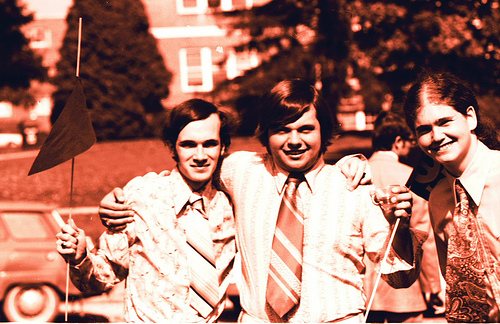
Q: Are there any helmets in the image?
A: No, there are no helmets.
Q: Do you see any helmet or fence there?
A: No, there are no helmets or fences.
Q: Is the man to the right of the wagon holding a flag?
A: Yes, the man is holding a flag.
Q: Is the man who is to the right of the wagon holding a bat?
A: No, the man is holding a flag.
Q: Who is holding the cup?
A: The man is holding the cup.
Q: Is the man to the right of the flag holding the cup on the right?
A: Yes, the man is holding the cup.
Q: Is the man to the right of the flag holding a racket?
A: No, the man is holding the cup.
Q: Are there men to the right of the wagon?
A: Yes, there is a man to the right of the wagon.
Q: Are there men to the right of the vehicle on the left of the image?
A: Yes, there is a man to the right of the wagon.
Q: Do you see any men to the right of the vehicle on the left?
A: Yes, there is a man to the right of the wagon.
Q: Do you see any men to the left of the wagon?
A: No, the man is to the right of the wagon.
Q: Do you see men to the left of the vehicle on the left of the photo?
A: No, the man is to the right of the wagon.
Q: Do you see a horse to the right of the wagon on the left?
A: No, there is a man to the right of the wagon.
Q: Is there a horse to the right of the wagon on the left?
A: No, there is a man to the right of the wagon.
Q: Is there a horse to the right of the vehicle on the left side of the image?
A: No, there is a man to the right of the wagon.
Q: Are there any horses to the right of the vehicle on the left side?
A: No, there is a man to the right of the wagon.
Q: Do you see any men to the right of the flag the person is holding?
A: Yes, there is a man to the right of the flag.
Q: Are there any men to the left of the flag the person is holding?
A: No, the man is to the right of the flag.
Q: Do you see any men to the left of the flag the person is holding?
A: No, the man is to the right of the flag.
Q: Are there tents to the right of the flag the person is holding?
A: No, there is a man to the right of the flag.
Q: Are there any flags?
A: Yes, there is a flag.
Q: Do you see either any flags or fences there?
A: Yes, there is a flag.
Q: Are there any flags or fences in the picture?
A: Yes, there is a flag.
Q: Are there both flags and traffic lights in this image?
A: No, there is a flag but no traffic lights.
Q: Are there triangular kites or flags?
A: Yes, there is a triangular flag.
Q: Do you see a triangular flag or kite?
A: Yes, there is a triangular flag.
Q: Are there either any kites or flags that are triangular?
A: Yes, the flag is triangular.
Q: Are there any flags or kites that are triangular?
A: Yes, the flag is triangular.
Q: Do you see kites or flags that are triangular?
A: Yes, the flag is triangular.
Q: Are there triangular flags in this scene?
A: Yes, there is a triangular flag.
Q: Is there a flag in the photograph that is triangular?
A: Yes, there is a flag that is triangular.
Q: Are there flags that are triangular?
A: Yes, there is a flag that is triangular.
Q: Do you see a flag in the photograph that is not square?
A: Yes, there is a triangular flag.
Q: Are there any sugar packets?
A: No, there are no sugar packets.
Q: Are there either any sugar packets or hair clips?
A: No, there are no sugar packets or hair clips.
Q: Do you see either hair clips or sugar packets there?
A: No, there are no sugar packets or hair clips.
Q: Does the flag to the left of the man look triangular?
A: Yes, the flag is triangular.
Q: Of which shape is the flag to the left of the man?
A: The flag is triangular.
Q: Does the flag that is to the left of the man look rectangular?
A: No, the flag is triangular.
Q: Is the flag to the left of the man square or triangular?
A: The flag is triangular.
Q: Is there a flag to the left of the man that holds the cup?
A: Yes, there is a flag to the left of the man.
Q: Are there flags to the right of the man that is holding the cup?
A: No, the flag is to the left of the man.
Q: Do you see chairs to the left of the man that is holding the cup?
A: No, there is a flag to the left of the man.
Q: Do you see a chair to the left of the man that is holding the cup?
A: No, there is a flag to the left of the man.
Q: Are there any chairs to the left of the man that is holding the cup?
A: No, there is a flag to the left of the man.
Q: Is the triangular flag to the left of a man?
A: Yes, the flag is to the left of a man.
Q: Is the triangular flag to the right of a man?
A: No, the flag is to the left of a man.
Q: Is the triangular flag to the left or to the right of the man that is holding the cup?
A: The flag is to the left of the man.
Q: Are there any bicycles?
A: No, there are no bicycles.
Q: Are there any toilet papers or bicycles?
A: No, there are no bicycles or toilet papers.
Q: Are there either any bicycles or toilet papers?
A: No, there are no bicycles or toilet papers.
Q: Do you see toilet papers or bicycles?
A: No, there are no bicycles or toilet papers.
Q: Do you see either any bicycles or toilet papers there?
A: No, there are no bicycles or toilet papers.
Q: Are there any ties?
A: Yes, there is a tie.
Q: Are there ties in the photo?
A: Yes, there is a tie.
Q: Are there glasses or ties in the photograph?
A: Yes, there is a tie.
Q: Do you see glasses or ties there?
A: Yes, there is a tie.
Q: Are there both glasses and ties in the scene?
A: Yes, there are both a tie and glasses.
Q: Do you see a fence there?
A: No, there are no fences.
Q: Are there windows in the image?
A: Yes, there is a window.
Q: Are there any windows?
A: Yes, there is a window.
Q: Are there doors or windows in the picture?
A: Yes, there is a window.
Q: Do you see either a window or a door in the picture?
A: Yes, there is a window.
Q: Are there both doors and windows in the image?
A: No, there is a window but no doors.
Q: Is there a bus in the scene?
A: No, there are no buses.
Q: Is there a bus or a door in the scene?
A: No, there are no buses or doors.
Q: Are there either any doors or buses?
A: No, there are no buses or doors.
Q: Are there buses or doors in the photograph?
A: No, there are no buses or doors.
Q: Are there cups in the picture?
A: Yes, there is a cup.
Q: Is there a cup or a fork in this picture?
A: Yes, there is a cup.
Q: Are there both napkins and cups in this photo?
A: No, there is a cup but no napkins.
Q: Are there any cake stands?
A: No, there are no cake stands.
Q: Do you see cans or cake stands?
A: No, there are no cake stands or cans.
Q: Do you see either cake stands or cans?
A: No, there are no cake stands or cans.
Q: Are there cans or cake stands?
A: No, there are no cake stands or cans.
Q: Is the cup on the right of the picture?
A: Yes, the cup is on the right of the image.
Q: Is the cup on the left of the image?
A: No, the cup is on the right of the image.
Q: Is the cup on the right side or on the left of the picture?
A: The cup is on the right of the image.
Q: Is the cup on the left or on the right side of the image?
A: The cup is on the right of the image.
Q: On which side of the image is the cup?
A: The cup is on the right of the image.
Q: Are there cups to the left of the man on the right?
A: Yes, there is a cup to the left of the man.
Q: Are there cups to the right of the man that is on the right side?
A: No, the cup is to the left of the man.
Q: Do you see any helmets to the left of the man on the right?
A: No, there is a cup to the left of the man.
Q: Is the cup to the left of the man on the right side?
A: Yes, the cup is to the left of the man.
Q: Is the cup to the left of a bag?
A: No, the cup is to the left of the man.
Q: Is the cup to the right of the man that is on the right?
A: No, the cup is to the left of the man.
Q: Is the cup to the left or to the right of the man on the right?
A: The cup is to the left of the man.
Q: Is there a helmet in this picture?
A: No, there are no helmets.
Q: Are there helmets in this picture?
A: No, there are no helmets.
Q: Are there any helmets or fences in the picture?
A: No, there are no helmets or fences.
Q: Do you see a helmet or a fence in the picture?
A: No, there are no helmets or fences.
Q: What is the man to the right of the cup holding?
A: The man is holding the flag.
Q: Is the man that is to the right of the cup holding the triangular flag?
A: Yes, the man is holding the flag.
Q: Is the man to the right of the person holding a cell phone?
A: No, the man is holding the flag.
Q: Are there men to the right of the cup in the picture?
A: Yes, there is a man to the right of the cup.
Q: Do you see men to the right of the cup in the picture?
A: Yes, there is a man to the right of the cup.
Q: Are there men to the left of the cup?
A: No, the man is to the right of the cup.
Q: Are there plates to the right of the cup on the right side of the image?
A: No, there is a man to the right of the cup.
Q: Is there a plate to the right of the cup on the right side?
A: No, there is a man to the right of the cup.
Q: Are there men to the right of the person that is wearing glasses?
A: Yes, there is a man to the right of the person.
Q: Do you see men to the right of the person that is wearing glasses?
A: Yes, there is a man to the right of the person.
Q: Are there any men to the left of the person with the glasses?
A: No, the man is to the right of the person.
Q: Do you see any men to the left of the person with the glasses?
A: No, the man is to the right of the person.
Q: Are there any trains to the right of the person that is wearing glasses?
A: No, there is a man to the right of the person.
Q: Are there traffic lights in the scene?
A: No, there are no traffic lights.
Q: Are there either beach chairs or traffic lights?
A: No, there are no traffic lights or beach chairs.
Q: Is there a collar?
A: Yes, there is a collar.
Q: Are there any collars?
A: Yes, there is a collar.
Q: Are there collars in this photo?
A: Yes, there is a collar.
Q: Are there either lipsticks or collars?
A: Yes, there is a collar.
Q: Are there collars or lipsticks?
A: Yes, there is a collar.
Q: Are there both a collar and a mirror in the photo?
A: No, there is a collar but no mirrors.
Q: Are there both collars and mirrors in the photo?
A: No, there is a collar but no mirrors.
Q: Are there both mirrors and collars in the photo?
A: No, there is a collar but no mirrors.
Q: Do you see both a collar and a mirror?
A: No, there is a collar but no mirrors.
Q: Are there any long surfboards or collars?
A: Yes, there is a long collar.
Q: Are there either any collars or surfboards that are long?
A: Yes, the collar is long.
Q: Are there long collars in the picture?
A: Yes, there is a long collar.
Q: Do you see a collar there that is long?
A: Yes, there is a collar that is long.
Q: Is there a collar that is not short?
A: Yes, there is a long collar.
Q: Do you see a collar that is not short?
A: Yes, there is a long collar.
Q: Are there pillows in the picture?
A: No, there are no pillows.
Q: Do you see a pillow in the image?
A: No, there are no pillows.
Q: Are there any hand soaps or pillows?
A: No, there are no pillows or hand soaps.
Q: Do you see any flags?
A: Yes, there is a flag.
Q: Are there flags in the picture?
A: Yes, there is a flag.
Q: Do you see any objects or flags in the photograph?
A: Yes, there is a flag.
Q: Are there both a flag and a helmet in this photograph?
A: No, there is a flag but no helmets.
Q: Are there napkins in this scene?
A: No, there are no napkins.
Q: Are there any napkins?
A: No, there are no napkins.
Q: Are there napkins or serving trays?
A: No, there are no napkins or serving trays.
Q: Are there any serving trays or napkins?
A: No, there are no napkins or serving trays.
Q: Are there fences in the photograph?
A: No, there are no fences.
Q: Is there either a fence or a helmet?
A: No, there are no fences or helmets.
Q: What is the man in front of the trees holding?
A: The man is holding the flag.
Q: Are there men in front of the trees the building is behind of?
A: Yes, there is a man in front of the trees.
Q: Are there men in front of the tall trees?
A: Yes, there is a man in front of the trees.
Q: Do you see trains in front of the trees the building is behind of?
A: No, there is a man in front of the trees.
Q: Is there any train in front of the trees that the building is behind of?
A: No, there is a man in front of the trees.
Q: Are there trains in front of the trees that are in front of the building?
A: No, there is a man in front of the trees.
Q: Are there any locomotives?
A: No, there are no locomotives.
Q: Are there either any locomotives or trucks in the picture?
A: No, there are no locomotives or trucks.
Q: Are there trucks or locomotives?
A: No, there are no locomotives or trucks.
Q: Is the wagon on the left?
A: Yes, the wagon is on the left of the image.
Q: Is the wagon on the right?
A: No, the wagon is on the left of the image.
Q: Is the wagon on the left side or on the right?
A: The wagon is on the left of the image.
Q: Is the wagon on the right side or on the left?
A: The wagon is on the left of the image.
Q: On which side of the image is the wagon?
A: The wagon is on the left of the image.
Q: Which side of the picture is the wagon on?
A: The wagon is on the left of the image.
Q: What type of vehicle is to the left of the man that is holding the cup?
A: The vehicle is a wagon.